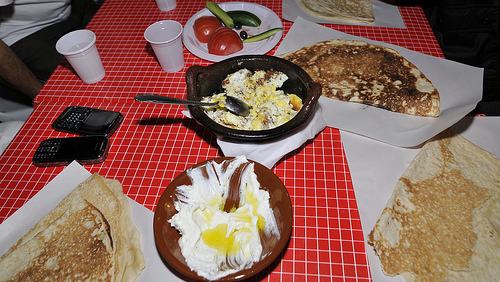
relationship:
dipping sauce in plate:
[180, 179, 256, 268] [140, 146, 312, 280]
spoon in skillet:
[133, 90, 250, 117] [182, 54, 324, 140]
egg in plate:
[198, 194, 265, 253] [152, 156, 293, 282]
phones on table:
[32, 132, 109, 167] [1, 0, 448, 280]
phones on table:
[48, 102, 123, 137] [1, 0, 448, 280]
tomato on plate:
[192, 10, 244, 57] [178, 4, 293, 64]